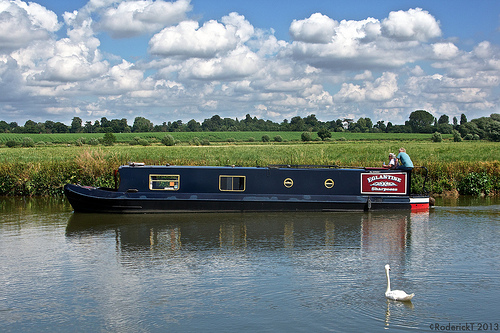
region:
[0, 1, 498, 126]
Cloudy daytime sky in back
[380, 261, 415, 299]
White duck swimming on water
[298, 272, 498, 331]
Round ripples in water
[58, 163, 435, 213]
Navy blue boat on water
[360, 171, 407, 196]
Sign on the side of boat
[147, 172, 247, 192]
Windows on side of boat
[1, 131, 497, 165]
Green grassy fields behind water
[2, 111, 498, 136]
Lines of trees behind fields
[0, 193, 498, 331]
Calm body of water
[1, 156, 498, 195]
Greenery and weeds on banks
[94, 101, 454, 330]
a boat in the water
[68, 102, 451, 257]
a large boat in the water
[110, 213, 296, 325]
a body of water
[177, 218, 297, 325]
a body of calm water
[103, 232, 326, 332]
a body of water that is calm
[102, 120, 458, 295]
a long blue boat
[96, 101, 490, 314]
a blue boat in the water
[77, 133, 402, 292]
a long boat in the water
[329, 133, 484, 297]
people on the boat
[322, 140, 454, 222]
opoeple on the blue boat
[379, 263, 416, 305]
A swan in the water.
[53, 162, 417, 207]
A navy blue boat.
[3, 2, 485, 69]
White fluffy clouds in the sky.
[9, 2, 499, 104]
Blue sky full of clouds.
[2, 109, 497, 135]
Line of dark green trees.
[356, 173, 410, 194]
Red and white sign on side of boat.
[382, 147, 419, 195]
People standing on back of boat.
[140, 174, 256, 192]
Windows on side of boat.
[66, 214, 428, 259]
Shadow of boat on the water.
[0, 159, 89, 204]
Grass growing along the water.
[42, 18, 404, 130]
the sky is cloudy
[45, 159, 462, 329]
the boat is blue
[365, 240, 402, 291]
a duck is in the water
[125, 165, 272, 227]
the boat has windows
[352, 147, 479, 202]
people are on the boat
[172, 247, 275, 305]
ripples are in the water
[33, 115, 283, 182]
trees are in the distance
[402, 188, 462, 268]
the dock is red and white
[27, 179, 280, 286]
the boat's reflection in the water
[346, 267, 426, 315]
the duck is white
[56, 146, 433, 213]
a canal packet boat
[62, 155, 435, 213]
a blue canal boat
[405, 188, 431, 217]
a red aft area with thite trim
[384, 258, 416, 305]
a curious swan swims by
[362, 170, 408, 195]
name of boat and it's home port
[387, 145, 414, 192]
anolder couple get out to see the view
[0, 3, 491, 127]
sky is full of non threatening clouds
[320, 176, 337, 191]
one of two round windows on the boat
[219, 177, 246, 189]
sliding glass rectangular window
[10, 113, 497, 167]
green fields and trees